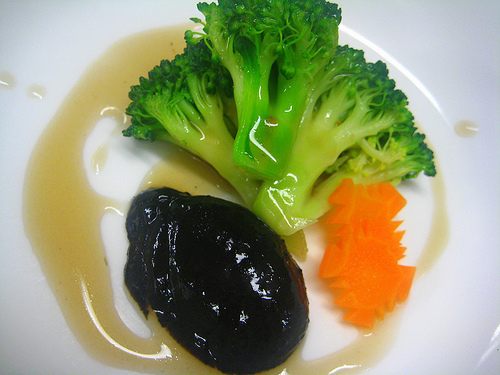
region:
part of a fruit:
[248, 270, 290, 331]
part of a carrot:
[337, 265, 381, 338]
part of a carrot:
[328, 252, 370, 316]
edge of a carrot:
[334, 265, 372, 340]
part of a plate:
[424, 290, 449, 327]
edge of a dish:
[445, 278, 478, 313]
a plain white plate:
[13, 1, 492, 363]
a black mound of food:
[108, 175, 330, 370]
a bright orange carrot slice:
[318, 173, 418, 332]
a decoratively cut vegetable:
[316, 212, 420, 329]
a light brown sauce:
[16, 131, 126, 355]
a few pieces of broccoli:
[118, 0, 440, 230]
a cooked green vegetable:
[145, 8, 446, 225]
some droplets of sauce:
[0, 69, 60, 115]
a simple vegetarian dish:
[105, 0, 477, 367]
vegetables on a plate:
[102, 0, 488, 350]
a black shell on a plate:
[152, 231, 305, 362]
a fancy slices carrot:
[319, 201, 378, 318]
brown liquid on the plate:
[39, 194, 90, 269]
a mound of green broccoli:
[216, 29, 363, 165]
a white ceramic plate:
[439, 287, 485, 354]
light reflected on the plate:
[387, 57, 413, 79]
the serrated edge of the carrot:
[331, 267, 353, 300]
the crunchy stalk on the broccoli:
[284, 118, 323, 182]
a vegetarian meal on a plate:
[62, 15, 426, 370]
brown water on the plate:
[53, 259, 111, 307]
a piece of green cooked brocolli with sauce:
[122, 52, 261, 201]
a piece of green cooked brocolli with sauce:
[195, 2, 326, 167]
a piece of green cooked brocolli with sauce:
[267, 48, 424, 227]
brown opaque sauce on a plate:
[22, 28, 458, 372]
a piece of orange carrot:
[322, 173, 418, 330]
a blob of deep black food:
[125, 193, 300, 368]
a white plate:
[1, 3, 498, 370]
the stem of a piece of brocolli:
[225, 64, 305, 172]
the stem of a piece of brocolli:
[189, 111, 267, 199]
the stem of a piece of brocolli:
[262, 113, 343, 232]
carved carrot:
[315, 170, 423, 336]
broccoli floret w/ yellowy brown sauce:
[253, 63, 448, 240]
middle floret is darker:
[180, 1, 347, 183]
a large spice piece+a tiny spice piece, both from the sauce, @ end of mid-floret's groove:
[258, 111, 281, 166]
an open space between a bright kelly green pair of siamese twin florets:
[260, 50, 282, 110]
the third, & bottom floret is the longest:
[120, 43, 317, 289]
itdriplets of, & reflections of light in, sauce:
[197, 121, 313, 267]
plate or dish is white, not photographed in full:
[0, 0, 497, 371]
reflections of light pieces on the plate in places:
[326, 16, 496, 371]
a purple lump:
[113, 181, 314, 373]